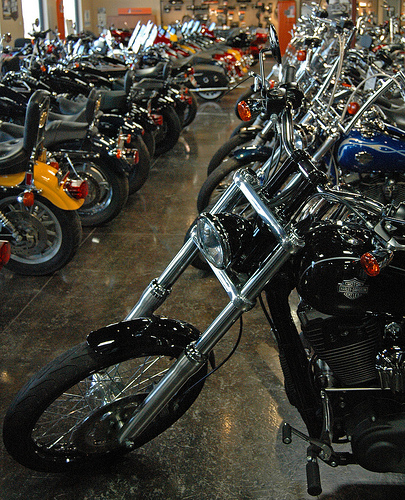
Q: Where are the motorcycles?
A: In a shop.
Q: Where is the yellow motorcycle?
A: On the left.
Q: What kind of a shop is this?
A: Motorcycle shop.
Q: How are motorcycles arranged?
A: In rows.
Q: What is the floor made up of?
A: Big tiles.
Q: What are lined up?
A: Motorcycles.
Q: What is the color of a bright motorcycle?
A: Yellow.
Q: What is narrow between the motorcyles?
A: The aisie.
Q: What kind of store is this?
A: A motorcycle store.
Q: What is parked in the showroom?
A: Motorcycles.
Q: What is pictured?
A: Many motorcycles.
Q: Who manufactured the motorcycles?
A: Harley Davidson.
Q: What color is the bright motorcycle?
A: Yellow.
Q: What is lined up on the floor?
A: Motorcycles.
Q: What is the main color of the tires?
A: Black.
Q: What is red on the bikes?
A: Brake lights.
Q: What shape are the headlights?
A: Circle.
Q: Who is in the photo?
A: No one.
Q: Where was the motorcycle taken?
A: Motorcycle shop.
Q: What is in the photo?
A: Motorcycles.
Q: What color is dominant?
A: Black.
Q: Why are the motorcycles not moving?
A: Because they are parked.